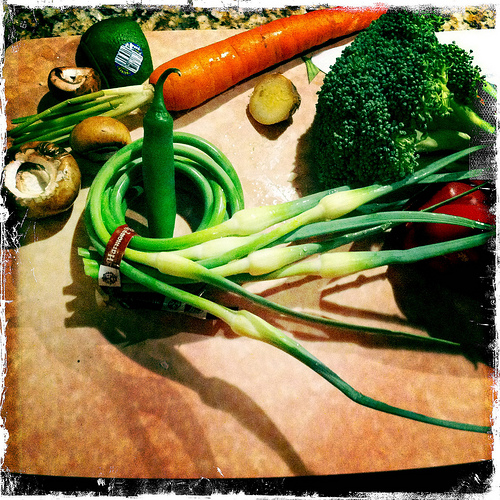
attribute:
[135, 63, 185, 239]
pepper — green, hot, maybe jalapeño, maybe serrano, standing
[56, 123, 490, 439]
vegetable — hard neck garlic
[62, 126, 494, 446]
hard neck garlic — green, tubed, maybe green onions, likely garlic though, mostly green, yellow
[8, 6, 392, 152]
carrot — large, orange, singular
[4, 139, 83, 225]
mushroom — stemless, cap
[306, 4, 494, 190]
broccoli — bunch, crown, fresh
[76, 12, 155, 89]
lime — lemon, cut, green, maybe avocado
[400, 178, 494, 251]
apple — red, maybe pepper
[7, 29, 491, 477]
cutting board — maybe table, brown, mottled brown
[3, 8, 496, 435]
vegetables — fresh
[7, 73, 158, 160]
top — once leaves, cut, "stem"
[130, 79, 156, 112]
stem — green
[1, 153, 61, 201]
underside — white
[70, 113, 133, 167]
mushroom — cap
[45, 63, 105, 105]
mushroom — cap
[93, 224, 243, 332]
twist tie — brown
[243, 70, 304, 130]
potato — halved, probably potato, maybe ginger, small\, golden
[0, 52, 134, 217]
mushrooms — three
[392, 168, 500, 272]
pepper — red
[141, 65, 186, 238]
jalapeño — thin, long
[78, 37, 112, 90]
seam — maybe cut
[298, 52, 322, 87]
leaf — of mystery vegetable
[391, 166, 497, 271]
mystery vegetable ii — red